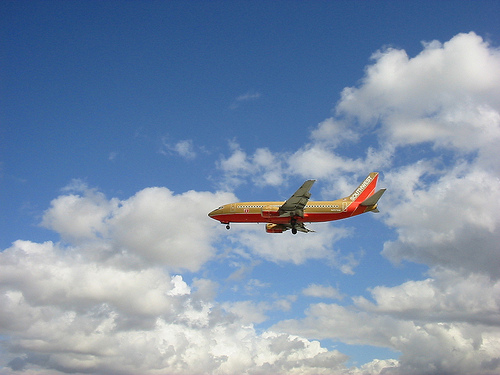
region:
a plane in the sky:
[141, 116, 436, 276]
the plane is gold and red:
[152, 128, 436, 253]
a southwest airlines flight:
[154, 107, 456, 289]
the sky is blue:
[56, 95, 189, 147]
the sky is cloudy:
[51, 72, 453, 309]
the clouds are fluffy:
[41, 87, 499, 334]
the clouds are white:
[71, 224, 196, 289]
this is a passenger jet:
[182, 165, 438, 285]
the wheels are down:
[158, 146, 469, 290]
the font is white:
[166, 125, 429, 271]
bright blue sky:
[13, 10, 322, 140]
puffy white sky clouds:
[3, 175, 268, 300]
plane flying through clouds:
[197, 192, 392, 256]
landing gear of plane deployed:
[217, 217, 328, 239]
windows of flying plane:
[225, 200, 339, 211]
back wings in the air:
[347, 173, 389, 213]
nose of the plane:
[201, 193, 230, 230]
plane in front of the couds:
[188, 158, 415, 280]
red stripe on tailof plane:
[312, 165, 397, 245]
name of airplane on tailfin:
[284, 167, 402, 204]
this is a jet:
[212, 192, 404, 232]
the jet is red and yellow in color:
[231, 201, 254, 224]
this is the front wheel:
[225, 225, 231, 230]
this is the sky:
[68, 30, 252, 131]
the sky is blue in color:
[79, 30, 146, 85]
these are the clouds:
[61, 248, 201, 353]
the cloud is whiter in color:
[135, 211, 210, 261]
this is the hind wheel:
[290, 225, 297, 236]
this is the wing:
[283, 183, 317, 218]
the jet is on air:
[211, 181, 364, 241]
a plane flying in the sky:
[180, 175, 441, 256]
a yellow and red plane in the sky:
[186, 165, 426, 263]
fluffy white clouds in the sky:
[20, 185, 187, 353]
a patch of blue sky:
[16, 25, 176, 118]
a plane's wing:
[283, 176, 319, 221]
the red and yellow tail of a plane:
[350, 166, 390, 222]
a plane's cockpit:
[200, 195, 233, 225]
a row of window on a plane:
[235, 201, 267, 207]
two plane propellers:
[262, 205, 282, 235]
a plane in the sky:
[61, 63, 466, 373]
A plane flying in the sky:
[208, 171, 387, 234]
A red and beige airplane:
[208, 170, 386, 236]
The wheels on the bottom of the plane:
[216, 220, 301, 235]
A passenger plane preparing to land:
[207, 172, 384, 236]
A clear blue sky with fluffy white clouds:
[0, 0, 499, 373]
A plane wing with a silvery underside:
[278, 178, 315, 216]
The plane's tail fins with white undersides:
[359, 187, 385, 214]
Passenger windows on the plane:
[233, 202, 340, 209]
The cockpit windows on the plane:
[213, 202, 227, 211]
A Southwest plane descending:
[207, 168, 387, 234]